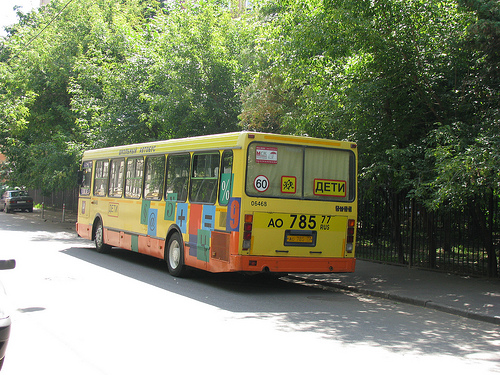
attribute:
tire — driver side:
[88, 218, 110, 254]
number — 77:
[316, 209, 336, 229]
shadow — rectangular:
[64, 225, 394, 364]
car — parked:
[3, 187, 46, 208]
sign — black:
[174, 205, 191, 233]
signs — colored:
[137, 190, 249, 268]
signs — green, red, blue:
[128, 172, 240, 267]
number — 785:
[285, 209, 318, 232]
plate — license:
[283, 235, 313, 244]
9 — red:
[227, 200, 238, 233]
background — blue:
[226, 199, 241, 233]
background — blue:
[199, 198, 216, 231]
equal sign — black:
[202, 210, 214, 229]